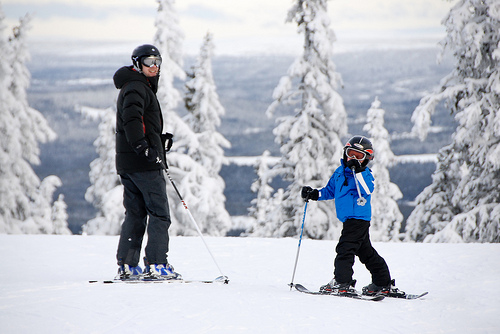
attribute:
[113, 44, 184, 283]
man — skiing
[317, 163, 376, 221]
parka — blue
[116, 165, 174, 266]
pants — black, grey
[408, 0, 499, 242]
tree — snowy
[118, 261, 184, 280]
boots — blue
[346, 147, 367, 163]
googles — orange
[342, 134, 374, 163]
helmet — black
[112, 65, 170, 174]
jacket — black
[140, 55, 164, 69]
goggles — black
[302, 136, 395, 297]
boy — small, skiing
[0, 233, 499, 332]
ground — covered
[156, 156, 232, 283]
pole — for balance, black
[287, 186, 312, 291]
ski pole — blue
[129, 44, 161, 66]
hat — black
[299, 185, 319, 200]
glove — black